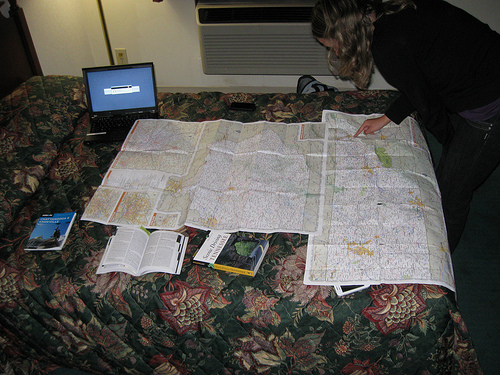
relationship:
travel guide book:
[40, 226, 64, 242] [28, 207, 65, 255]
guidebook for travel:
[195, 237, 268, 281] [40, 226, 64, 242]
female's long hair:
[314, 0, 484, 130] [332, 1, 381, 83]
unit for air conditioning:
[185, 14, 294, 74] [256, 2, 300, 23]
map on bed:
[120, 122, 321, 235] [0, 270, 431, 365]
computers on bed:
[75, 59, 166, 149] [0, 270, 431, 365]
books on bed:
[30, 213, 261, 288] [0, 270, 431, 365]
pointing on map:
[352, 131, 367, 138] [326, 110, 451, 287]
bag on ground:
[286, 71, 332, 92] [286, 93, 292, 95]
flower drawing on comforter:
[13, 120, 70, 177] [8, 114, 82, 173]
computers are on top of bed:
[82, 65, 257, 133] [0, 270, 431, 365]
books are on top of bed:
[30, 213, 261, 288] [0, 270, 431, 365]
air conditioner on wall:
[198, 6, 327, 77] [138, 8, 195, 64]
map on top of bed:
[120, 122, 321, 235] [0, 270, 431, 365]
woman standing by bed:
[314, 0, 484, 130] [0, 270, 431, 365]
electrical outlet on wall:
[108, 46, 134, 67] [138, 8, 195, 64]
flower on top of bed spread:
[31, 147, 50, 161] [24, 139, 85, 172]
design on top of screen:
[100, 85, 142, 97] [75, 70, 156, 105]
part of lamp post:
[108, 57, 113, 65] [87, 0, 115, 64]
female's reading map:
[304, 0, 500, 257] [326, 110, 451, 287]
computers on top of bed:
[75, 59, 166, 149] [0, 270, 431, 365]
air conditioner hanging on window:
[198, 6, 327, 77] [177, 0, 235, 5]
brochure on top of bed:
[326, 282, 374, 302] [0, 270, 431, 365]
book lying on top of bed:
[28, 207, 65, 255] [0, 270, 431, 365]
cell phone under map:
[223, 95, 255, 113] [120, 122, 321, 235]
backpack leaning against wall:
[286, 71, 332, 92] [138, 8, 195, 64]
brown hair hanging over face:
[337, 55, 368, 85] [323, 43, 349, 58]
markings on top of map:
[341, 238, 379, 253] [120, 122, 321, 235]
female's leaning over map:
[304, 0, 500, 257] [120, 122, 321, 235]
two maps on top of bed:
[118, 124, 430, 272] [0, 270, 431, 365]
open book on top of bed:
[96, 230, 185, 282] [0, 270, 431, 365]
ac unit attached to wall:
[185, 14, 294, 74] [138, 8, 195, 64]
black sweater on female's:
[400, 44, 487, 93] [304, 0, 500, 257]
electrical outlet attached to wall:
[108, 44, 139, 65] [138, 8, 195, 64]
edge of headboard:
[13, 8, 53, 74] [3, 28, 28, 86]